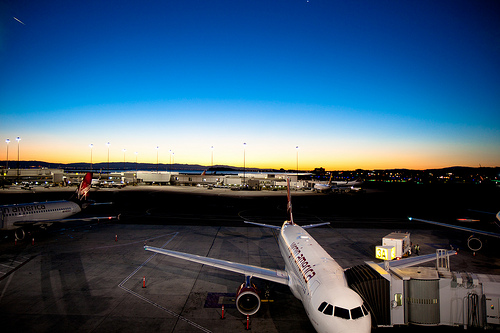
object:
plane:
[140, 179, 481, 333]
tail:
[239, 177, 334, 230]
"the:
[371, 231, 417, 261]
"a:
[348, 166, 496, 200]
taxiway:
[364, 173, 495, 206]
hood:
[141, 177, 380, 332]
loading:
[350, 249, 497, 332]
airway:
[1, 149, 497, 168]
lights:
[0, 143, 500, 178]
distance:
[1, 142, 500, 187]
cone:
[139, 274, 149, 289]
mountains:
[0, 159, 497, 176]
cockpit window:
[331, 304, 348, 318]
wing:
[35, 212, 124, 225]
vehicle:
[0, 180, 378, 198]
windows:
[1, 197, 122, 228]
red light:
[104, 215, 113, 222]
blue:
[0, 122, 497, 166]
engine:
[230, 270, 266, 317]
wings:
[141, 244, 289, 286]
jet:
[142, 177, 458, 331]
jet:
[0, 187, 121, 235]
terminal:
[0, 164, 362, 199]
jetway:
[368, 259, 498, 333]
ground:
[0, 189, 500, 329]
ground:
[2, 185, 482, 331]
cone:
[131, 269, 148, 293]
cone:
[220, 304, 229, 320]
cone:
[242, 311, 252, 331]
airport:
[0, 170, 324, 198]